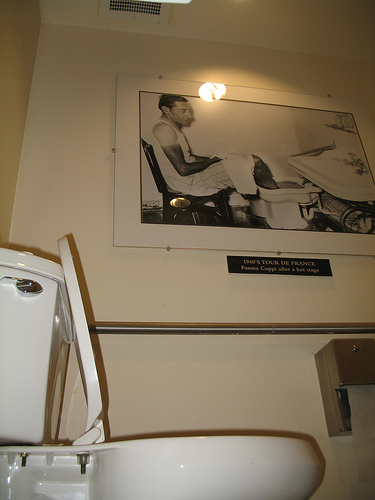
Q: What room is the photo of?
A: Bathroom.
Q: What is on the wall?
A: A photo.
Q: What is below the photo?
A: A plaque.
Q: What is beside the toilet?
A: A handrail.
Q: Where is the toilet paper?
A: In the dispenser.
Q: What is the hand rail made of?
A: Metal.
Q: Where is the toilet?
A: In the bathroom.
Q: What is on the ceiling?
A: The vent.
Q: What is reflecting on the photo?
A: The light.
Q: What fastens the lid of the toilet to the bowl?
A: Screw.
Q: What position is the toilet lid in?
A: Up.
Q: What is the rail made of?
A: Metal.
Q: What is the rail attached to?
A: The wall.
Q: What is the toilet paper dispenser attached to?
A: The wall.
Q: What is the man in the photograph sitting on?
A: A chair.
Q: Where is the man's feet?
A: In the toilet in the photograph.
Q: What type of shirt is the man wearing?
A: Muscle shirt.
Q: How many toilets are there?
A: One.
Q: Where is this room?
A: Bathroom.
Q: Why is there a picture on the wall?
A: Decoration.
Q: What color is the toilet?
A: White.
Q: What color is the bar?
A: Silver.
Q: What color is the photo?
A: Black and white.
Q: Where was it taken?
A: In a bathroom.